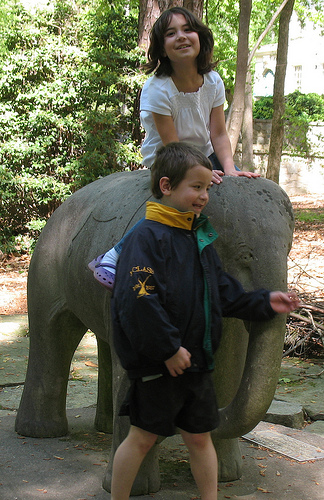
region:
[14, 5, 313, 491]
children near elephant statue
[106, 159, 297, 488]
child standing near elephant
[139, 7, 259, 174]
child sitting on elephant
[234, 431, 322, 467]
plaque on the ground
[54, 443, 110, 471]
leaves near the elephant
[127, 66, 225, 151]
shirt on the girl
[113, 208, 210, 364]
jacket on the boy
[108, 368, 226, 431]
shorts on the boy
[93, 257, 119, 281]
shoe on the girl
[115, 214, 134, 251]
pants on the girl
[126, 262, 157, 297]
yellow logo on the jacket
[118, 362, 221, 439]
boy is wearing shorts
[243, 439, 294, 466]
brown leaves on the ground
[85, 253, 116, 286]
a purple slip on shoe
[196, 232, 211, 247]
two buttons on the collar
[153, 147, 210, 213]
little boy is smiling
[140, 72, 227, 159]
a white shirt on the girl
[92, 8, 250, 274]
girl is sitting on a statue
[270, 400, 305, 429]
large stone on the ground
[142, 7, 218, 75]
the little girl has brown hair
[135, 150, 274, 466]
A boy by the statue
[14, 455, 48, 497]
A grey park floor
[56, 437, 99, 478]
A grey park floor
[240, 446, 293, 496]
A grey park floor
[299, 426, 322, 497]
A grey park floor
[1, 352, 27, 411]
A grey park floor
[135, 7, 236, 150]
A small girl smilling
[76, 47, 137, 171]
A green tree in a forest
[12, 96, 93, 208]
A green tree in a forest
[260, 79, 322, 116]
A green tree in a forest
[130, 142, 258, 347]
A young boy near a elephant statue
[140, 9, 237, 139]
A young girl smiling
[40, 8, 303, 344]
A young boy and girl near a elephant statue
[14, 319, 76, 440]
Leg of a elephant statue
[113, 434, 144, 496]
Leg of a young boy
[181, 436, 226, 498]
Leg of a young boy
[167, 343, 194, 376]
Hand of a young boy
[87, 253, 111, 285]
A young girl's purple sandal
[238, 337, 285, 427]
Trunk of a elephant statue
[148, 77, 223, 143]
White shirt being worn by a girl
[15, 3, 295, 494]
Girl sitting on an elephant statue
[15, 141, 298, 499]
Boy standing next to a statue of an elephant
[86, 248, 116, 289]
Purple shoe on girl's foot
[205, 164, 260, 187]
Girl's hands on elephant's head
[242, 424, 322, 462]
Plaque on the ground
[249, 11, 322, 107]
Building behind the trees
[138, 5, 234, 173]
Brunette girl wearing a white short-sleeved blouse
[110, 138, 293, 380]
Boy wearing a blue jacket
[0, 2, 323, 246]
Trees behind the children and elephant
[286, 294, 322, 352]
Twigs on the ground